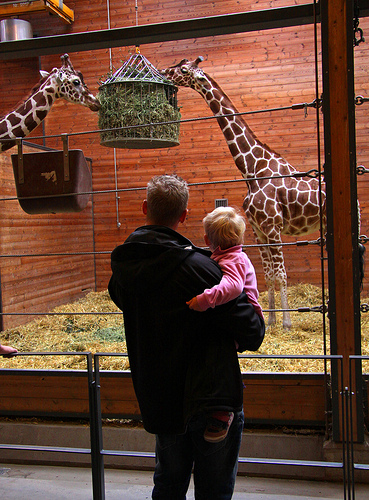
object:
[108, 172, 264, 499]
person's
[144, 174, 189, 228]
hair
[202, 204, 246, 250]
hair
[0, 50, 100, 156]
giraffe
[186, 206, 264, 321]
baby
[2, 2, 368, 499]
enclosure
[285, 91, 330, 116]
metal bolt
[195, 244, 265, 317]
sweater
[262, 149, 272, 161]
brown spot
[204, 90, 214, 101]
spot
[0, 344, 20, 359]
hand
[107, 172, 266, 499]
someone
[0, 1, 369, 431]
guard railing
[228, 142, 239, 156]
spot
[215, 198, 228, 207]
vent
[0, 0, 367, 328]
wall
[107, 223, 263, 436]
jacket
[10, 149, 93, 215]
bucket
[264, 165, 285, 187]
spot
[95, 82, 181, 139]
hay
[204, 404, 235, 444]
shoes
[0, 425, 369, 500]
cement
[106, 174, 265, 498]
man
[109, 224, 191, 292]
hood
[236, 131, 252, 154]
spot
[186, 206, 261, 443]
child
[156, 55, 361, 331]
giraffe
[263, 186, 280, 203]
brown spot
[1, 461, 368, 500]
floor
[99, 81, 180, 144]
grass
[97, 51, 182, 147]
cage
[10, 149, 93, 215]
food container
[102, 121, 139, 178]
bad sentence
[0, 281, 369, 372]
straw